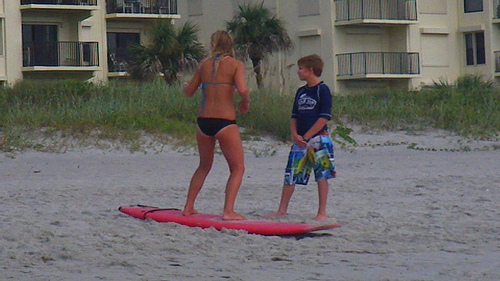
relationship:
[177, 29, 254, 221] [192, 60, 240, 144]
girl wearing bikini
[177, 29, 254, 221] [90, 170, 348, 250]
girl standing on surfboard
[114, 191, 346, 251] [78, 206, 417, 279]
surfboard on sand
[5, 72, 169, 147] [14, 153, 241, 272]
grass behind sand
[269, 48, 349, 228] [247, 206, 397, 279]
boy on sand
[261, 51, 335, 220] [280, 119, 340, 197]
boy wearing shorts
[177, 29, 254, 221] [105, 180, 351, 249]
girl on a surfboard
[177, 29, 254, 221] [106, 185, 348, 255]
girl on a surfboard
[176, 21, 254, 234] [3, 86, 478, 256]
girl at beach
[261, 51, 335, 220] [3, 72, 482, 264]
boy at beach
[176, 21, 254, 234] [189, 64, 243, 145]
girl wearing bikini